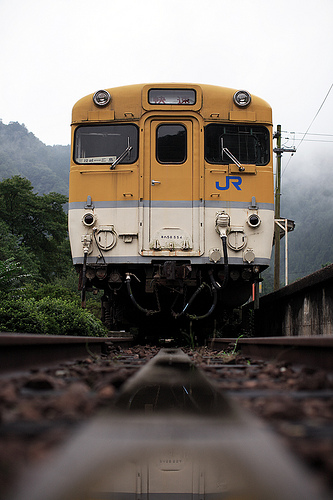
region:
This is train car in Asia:
[67, 80, 274, 281]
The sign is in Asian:
[147, 85, 199, 107]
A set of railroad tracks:
[49, 333, 301, 362]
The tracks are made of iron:
[62, 333, 310, 361]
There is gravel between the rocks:
[107, 343, 252, 370]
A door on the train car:
[133, 103, 209, 254]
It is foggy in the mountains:
[285, 123, 332, 206]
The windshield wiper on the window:
[215, 130, 252, 177]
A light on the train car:
[92, 87, 111, 105]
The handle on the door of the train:
[146, 170, 166, 194]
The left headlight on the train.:
[94, 90, 115, 106]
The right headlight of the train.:
[229, 88, 252, 111]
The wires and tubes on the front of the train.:
[75, 262, 253, 325]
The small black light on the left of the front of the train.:
[76, 213, 96, 224]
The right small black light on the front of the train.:
[240, 217, 261, 230]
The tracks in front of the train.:
[32, 296, 331, 499]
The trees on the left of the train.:
[6, 170, 83, 330]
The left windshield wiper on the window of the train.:
[103, 132, 135, 170]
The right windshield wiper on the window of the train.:
[215, 130, 245, 171]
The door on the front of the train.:
[145, 112, 203, 245]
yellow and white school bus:
[70, 97, 258, 237]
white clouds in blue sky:
[12, 5, 56, 43]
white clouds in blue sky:
[5, 47, 48, 89]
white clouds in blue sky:
[30, 91, 55, 124]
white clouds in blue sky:
[293, 155, 329, 187]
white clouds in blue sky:
[286, 52, 318, 93]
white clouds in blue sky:
[48, 9, 113, 64]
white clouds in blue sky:
[113, 6, 162, 82]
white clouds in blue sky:
[171, 12, 203, 67]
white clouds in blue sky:
[220, 12, 268, 95]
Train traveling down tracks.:
[68, 82, 273, 331]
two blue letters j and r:
[202, 167, 250, 204]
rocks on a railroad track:
[40, 328, 301, 409]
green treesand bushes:
[2, 230, 79, 329]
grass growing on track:
[190, 327, 257, 378]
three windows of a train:
[65, 113, 296, 186]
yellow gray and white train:
[33, 139, 188, 294]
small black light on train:
[227, 212, 273, 236]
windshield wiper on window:
[193, 125, 267, 181]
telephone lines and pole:
[250, 118, 316, 264]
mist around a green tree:
[254, 159, 330, 277]